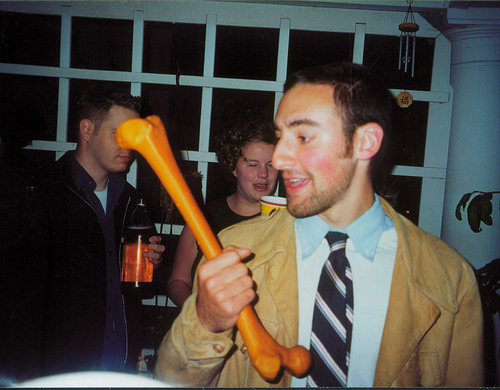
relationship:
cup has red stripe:
[262, 194, 288, 218] [260, 193, 288, 208]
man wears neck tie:
[154, 61, 485, 387] [311, 230, 354, 388]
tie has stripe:
[311, 230, 354, 388] [307, 240, 351, 388]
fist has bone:
[198, 244, 258, 328] [116, 115, 311, 381]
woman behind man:
[167, 116, 280, 308] [154, 61, 485, 387]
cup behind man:
[262, 194, 288, 218] [154, 61, 485, 387]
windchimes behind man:
[399, 2, 418, 79] [154, 61, 485, 387]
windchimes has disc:
[399, 2, 418, 79] [399, 23, 419, 32]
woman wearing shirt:
[167, 116, 280, 308] [188, 194, 263, 252]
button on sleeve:
[214, 342, 225, 353] [152, 292, 233, 385]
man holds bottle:
[2, 92, 167, 377] [120, 195, 156, 298]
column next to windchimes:
[436, 7, 499, 274] [399, 2, 418, 79]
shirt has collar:
[294, 191, 400, 387] [291, 194, 395, 262]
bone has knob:
[116, 115, 311, 381] [118, 113, 154, 149]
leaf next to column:
[455, 191, 470, 220] [436, 7, 499, 274]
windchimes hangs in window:
[399, 2, 418, 79] [359, 32, 436, 92]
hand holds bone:
[198, 244, 258, 328] [116, 115, 311, 381]